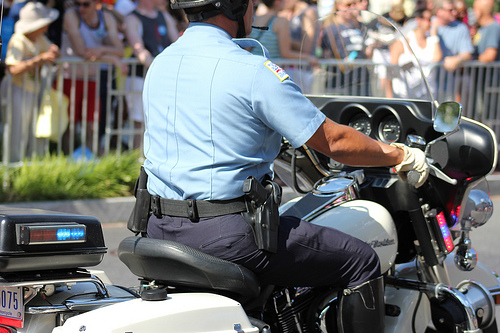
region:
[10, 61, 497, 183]
a silver gate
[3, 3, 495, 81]
people standing behind a gate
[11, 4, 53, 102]
a person wearing a hat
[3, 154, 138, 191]
tall grass next to the street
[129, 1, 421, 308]
a police officer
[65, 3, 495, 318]
a cop on a motorcycle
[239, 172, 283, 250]
the gun on the cop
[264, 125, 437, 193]
the handlebars on the motorcycle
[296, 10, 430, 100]
the windshield on the motorcycle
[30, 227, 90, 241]
a blue light on the motorcycle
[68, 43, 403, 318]
a man on a bike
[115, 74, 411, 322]
a man on a motorcycle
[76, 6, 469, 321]
an officer on a bike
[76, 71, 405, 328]
an officer on a motorcycle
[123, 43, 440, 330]
a police officer on a bike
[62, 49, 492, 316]
a police officer on a motorcycle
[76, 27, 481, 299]
a man riding a bike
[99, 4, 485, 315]
a man riding a motorcycle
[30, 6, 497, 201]
people standing behind a fence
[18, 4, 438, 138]
people standing behind a metal fence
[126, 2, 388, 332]
A cop on a motorcycle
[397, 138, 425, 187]
The cop is wearing a glove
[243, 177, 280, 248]
A gun in the holster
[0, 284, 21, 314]
A license plate on the motorcycle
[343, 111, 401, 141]
Odometers on the motorcycle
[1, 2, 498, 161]
Spectators watching the parade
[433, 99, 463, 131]
A mirror on the motorcycle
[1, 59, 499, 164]
A fence by the spectators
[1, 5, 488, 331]
A motorcycle beneath the cop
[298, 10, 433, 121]
A windshield on the motorcycle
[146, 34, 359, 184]
the shirt is blue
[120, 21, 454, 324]
the man is sitting on the bike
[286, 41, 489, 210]
a visor on the bike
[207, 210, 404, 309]
the pants are blue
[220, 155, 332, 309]
the man has a gun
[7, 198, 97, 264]
a light is on the motorcycle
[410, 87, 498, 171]
a light is on the motorcycle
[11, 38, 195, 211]
people are behind a gate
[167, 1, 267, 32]
the man is wearing his helmet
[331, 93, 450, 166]
an odometer is on the bike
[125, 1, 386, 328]
a police officer riding a motorcycle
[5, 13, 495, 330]
a police motorcycle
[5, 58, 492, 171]
a metal temporary fence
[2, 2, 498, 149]
a large crowd behind a fence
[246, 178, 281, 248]
the officer's gun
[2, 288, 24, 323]
the motorcycle's license plate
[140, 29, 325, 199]
the officer's blue shirt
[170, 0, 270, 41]
the officer's helmet and microphone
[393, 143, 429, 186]
white glove on the officer's hand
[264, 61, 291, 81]
patch on the officer's right sleeve